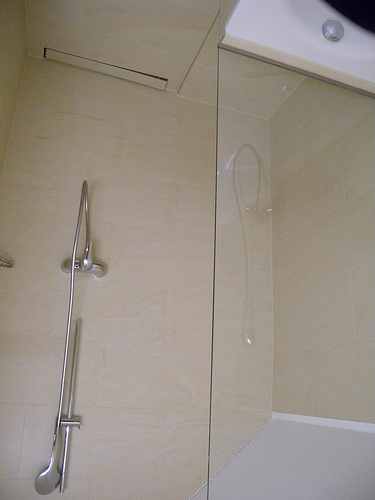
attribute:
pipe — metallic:
[35, 411, 70, 497]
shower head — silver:
[33, 463, 64, 496]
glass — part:
[210, 366, 272, 433]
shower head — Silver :
[35, 435, 62, 494]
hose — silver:
[32, 178, 106, 495]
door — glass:
[256, 367, 286, 421]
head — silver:
[32, 400, 80, 499]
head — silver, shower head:
[34, 182, 106, 498]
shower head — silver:
[30, 411, 84, 497]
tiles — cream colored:
[106, 402, 181, 489]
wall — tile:
[99, 100, 181, 192]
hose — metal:
[49, 172, 95, 438]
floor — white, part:
[191, 417, 373, 497]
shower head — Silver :
[318, 15, 361, 61]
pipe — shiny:
[34, 178, 92, 494]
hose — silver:
[38, 179, 95, 498]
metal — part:
[55, 172, 108, 365]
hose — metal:
[8, 168, 96, 312]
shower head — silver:
[33, 430, 63, 494]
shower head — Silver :
[18, 419, 91, 498]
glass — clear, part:
[205, 44, 373, 496]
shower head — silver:
[32, 436, 64, 494]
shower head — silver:
[32, 454, 66, 494]